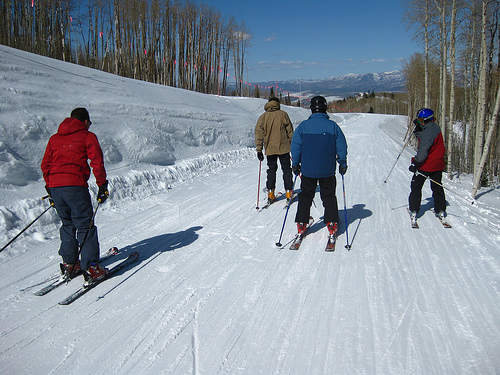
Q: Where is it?
A: This is at the field.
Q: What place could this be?
A: It is a field.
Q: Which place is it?
A: It is a field.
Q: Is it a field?
A: Yes, it is a field.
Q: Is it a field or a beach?
A: It is a field.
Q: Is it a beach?
A: No, it is a field.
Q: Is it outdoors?
A: Yes, it is outdoors.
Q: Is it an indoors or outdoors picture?
A: It is outdoors.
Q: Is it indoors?
A: No, it is outdoors.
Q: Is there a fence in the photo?
A: No, there are no fences.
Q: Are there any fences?
A: No, there are no fences.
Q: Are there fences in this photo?
A: No, there are no fences.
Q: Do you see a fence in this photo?
A: No, there are no fences.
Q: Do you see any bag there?
A: No, there are no bags.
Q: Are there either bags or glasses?
A: No, there are no bags or glasses.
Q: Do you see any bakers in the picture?
A: No, there are no bakers.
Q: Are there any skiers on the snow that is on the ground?
A: Yes, there is a skier on the snow.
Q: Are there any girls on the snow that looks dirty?
A: No, there is a skier on the snow.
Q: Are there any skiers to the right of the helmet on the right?
A: No, the skier is to the left of the helmet.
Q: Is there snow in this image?
A: Yes, there is snow.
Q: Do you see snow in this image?
A: Yes, there is snow.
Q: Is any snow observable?
A: Yes, there is snow.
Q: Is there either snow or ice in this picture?
A: Yes, there is snow.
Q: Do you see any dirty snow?
A: Yes, there is dirty snow.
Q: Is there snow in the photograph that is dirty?
A: Yes, there is snow that is dirty.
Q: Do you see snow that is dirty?
A: Yes, there is snow that is dirty.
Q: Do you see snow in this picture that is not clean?
A: Yes, there is dirty snow.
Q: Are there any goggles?
A: No, there are no goggles.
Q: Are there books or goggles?
A: No, there are no goggles or books.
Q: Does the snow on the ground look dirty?
A: Yes, the snow is dirty.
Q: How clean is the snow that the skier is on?
A: The snow is dirty.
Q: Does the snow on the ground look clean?
A: No, the snow is dirty.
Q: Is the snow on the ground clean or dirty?
A: The snow is dirty.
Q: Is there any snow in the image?
A: Yes, there is snow.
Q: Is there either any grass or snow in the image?
A: Yes, there is snow.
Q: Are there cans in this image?
A: No, there are no cans.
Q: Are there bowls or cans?
A: No, there are no cans or bowls.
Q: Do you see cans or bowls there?
A: No, there are no cans or bowls.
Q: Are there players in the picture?
A: No, there are no players.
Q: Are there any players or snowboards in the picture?
A: No, there are no players or snowboards.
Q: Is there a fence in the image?
A: No, there are no fences.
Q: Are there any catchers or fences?
A: No, there are no fences or catchers.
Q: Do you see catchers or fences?
A: No, there are no fences or catchers.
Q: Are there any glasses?
A: No, there are no glasses.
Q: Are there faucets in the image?
A: No, there are no faucets.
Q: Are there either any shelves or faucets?
A: No, there are no faucets or shelves.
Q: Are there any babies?
A: No, there are no babies.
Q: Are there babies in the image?
A: No, there are no babies.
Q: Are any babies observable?
A: No, there are no babies.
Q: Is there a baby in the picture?
A: No, there are no babies.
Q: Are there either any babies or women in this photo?
A: No, there are no babies or women.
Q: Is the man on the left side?
A: Yes, the man is on the left of the image.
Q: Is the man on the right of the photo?
A: No, the man is on the left of the image.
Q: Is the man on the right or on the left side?
A: The man is on the left of the image.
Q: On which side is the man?
A: The man is on the left of the image.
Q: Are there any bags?
A: No, there are no bags.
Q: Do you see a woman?
A: No, there are no women.